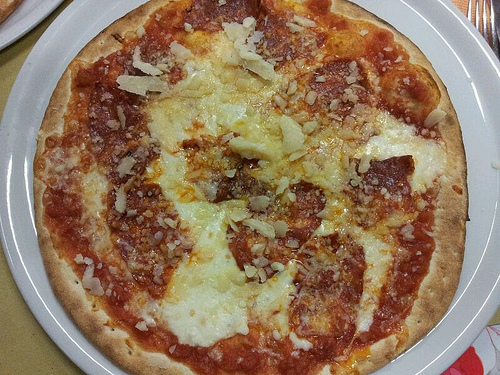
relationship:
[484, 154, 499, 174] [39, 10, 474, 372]
parmesan on plate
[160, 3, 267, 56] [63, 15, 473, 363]
meat on pizza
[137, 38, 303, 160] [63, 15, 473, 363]
cheese on pizza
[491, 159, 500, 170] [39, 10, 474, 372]
parmesan on plate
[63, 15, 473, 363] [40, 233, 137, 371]
pizza has edge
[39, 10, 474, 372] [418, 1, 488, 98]
plate has inside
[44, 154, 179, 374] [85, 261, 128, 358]
crust has holes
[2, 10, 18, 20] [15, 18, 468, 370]
crust of a pizza